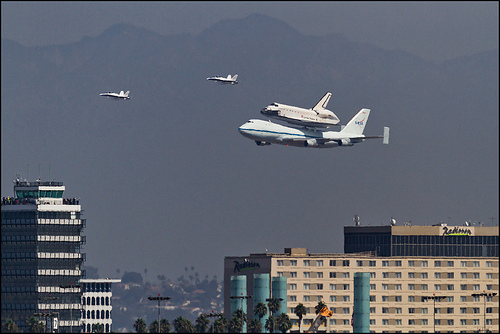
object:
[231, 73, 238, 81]
tail fin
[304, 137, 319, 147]
engine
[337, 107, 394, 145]
wing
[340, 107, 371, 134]
fin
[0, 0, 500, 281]
sky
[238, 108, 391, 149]
airplane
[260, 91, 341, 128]
airplane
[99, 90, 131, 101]
air plane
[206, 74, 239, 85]
air plane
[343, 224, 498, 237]
roof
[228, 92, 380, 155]
shuttle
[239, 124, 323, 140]
line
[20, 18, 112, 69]
white clouds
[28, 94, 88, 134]
white clouds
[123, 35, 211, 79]
white clouds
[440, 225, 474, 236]
hotel name